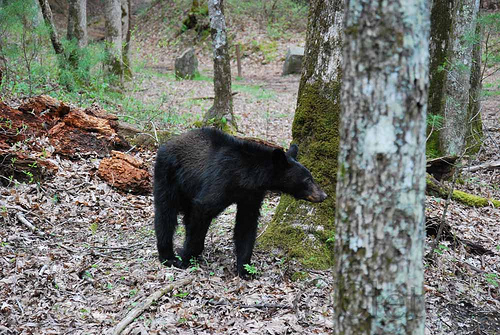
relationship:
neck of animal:
[266, 143, 294, 201] [151, 126, 327, 281]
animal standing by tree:
[151, 126, 327, 281] [335, 0, 434, 333]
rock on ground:
[287, 42, 329, 69] [3, 5, 494, 333]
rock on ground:
[162, 46, 258, 101] [3, 5, 494, 333]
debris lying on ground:
[107, 272, 199, 332] [4, 175, 499, 332]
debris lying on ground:
[117, 274, 140, 287] [4, 175, 499, 332]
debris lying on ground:
[90, 247, 127, 263] [4, 175, 499, 332]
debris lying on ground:
[91, 241, 130, 251] [4, 175, 499, 332]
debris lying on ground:
[35, 261, 50, 276] [4, 175, 499, 332]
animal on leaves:
[151, 126, 327, 281] [44, 204, 316, 316]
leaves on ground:
[13, 192, 338, 328] [15, 103, 498, 323]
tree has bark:
[331, 3, 467, 331] [358, 122, 398, 194]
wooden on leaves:
[19, 92, 144, 153] [0, 12, 500, 334]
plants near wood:
[3, 1, 123, 126] [6, 6, 144, 80]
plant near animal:
[242, 262, 257, 277] [151, 126, 327, 281]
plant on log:
[458, 188, 482, 205] [416, 152, 489, 219]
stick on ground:
[106, 273, 194, 333] [7, 60, 499, 326]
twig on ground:
[44, 189, 65, 211] [10, 170, 130, 304]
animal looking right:
[151, 126, 327, 281] [326, 10, 426, 333]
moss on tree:
[258, 65, 365, 272] [291, 30, 452, 302]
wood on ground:
[0, 92, 126, 180] [7, 60, 499, 326]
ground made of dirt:
[7, 60, 499, 326] [1, 65, 496, 325]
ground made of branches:
[7, 60, 499, 326] [1, 81, 497, 327]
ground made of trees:
[7, 60, 499, 326] [3, 67, 498, 328]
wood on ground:
[28, 97, 56, 123] [64, 164, 106, 208]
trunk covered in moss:
[255, 1, 349, 263] [258, 78, 338, 265]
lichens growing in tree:
[253, 73, 339, 272] [260, 2, 337, 270]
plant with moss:
[256, 0, 341, 280] [256, 83, 338, 281]